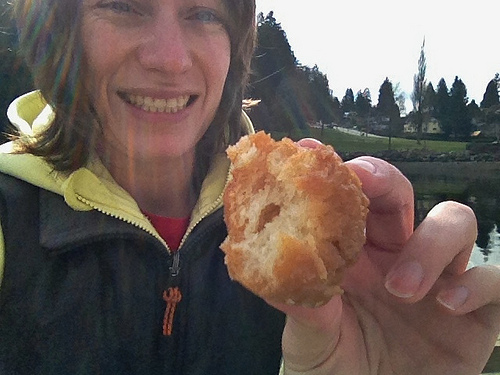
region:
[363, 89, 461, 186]
Trees are green in color.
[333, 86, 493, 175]
Trees are behind the lady.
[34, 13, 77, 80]
Hair is blonde.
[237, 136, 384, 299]
The cake is brown in color.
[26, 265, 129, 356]
Jacket is black in color.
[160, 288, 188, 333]
Brown color rope is tied to the zip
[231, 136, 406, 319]
lady is holding the cake piece.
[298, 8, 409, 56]
Sky is white in color.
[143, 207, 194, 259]
red color shirt inside her jacket.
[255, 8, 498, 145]
Trees in the background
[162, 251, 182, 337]
Zipper for the woman's jacket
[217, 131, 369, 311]
Piece of food the woman is holding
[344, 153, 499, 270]
Body of water behind the woman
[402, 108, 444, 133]
Building in the distance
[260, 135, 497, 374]
The woman's hand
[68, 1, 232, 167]
The woman's face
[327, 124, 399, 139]
A road in the background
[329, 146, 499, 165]
Rocks that line the shore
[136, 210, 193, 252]
Woman's red undershirt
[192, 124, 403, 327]
Golden toasted piece of food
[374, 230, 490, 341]
Neat shiny finger nails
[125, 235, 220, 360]
Zipper with orange pull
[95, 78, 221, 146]
Wide toothy smile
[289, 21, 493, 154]
House surrounded by tall trees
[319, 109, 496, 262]
Small body of water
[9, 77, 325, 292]
Dark grey jacket with yellow insert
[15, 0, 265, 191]
Smiling woman with short hair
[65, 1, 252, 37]
Woman's light blue eyes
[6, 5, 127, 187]
Short, dirty blond hair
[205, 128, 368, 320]
a donut hole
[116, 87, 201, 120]
the woman's teeth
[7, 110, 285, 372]
a blue and yellow jacket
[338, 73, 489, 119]
many tall trees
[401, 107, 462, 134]
a large house in the distance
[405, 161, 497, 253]
the water of a lake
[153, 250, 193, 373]
the zipper of a jacket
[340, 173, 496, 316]
the fingers of the woman's hand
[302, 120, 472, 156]
the green grass under the trees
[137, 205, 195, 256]
the top of a red shirt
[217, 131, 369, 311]
piece of bready food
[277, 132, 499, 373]
woman's left hand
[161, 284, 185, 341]
orange colored zipper pull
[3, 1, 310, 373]
woman smiling at camera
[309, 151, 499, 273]
lake behind the woman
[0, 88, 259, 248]
yellow hood of a jacket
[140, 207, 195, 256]
red shirt under the woman's jacket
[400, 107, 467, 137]
yellow colored house beyond the lake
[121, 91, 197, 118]
woman's teeth show in a smile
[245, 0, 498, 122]
a clear white sky